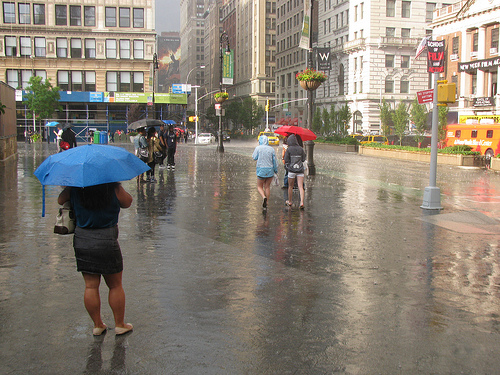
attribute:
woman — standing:
[57, 183, 133, 335]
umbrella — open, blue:
[36, 142, 151, 219]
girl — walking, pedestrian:
[280, 133, 307, 210]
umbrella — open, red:
[271, 123, 317, 143]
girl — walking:
[251, 130, 278, 211]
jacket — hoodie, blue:
[249, 134, 277, 178]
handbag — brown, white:
[52, 203, 73, 234]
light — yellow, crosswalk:
[187, 114, 194, 123]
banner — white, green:
[297, 0, 314, 52]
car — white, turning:
[194, 131, 216, 146]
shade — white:
[85, 72, 94, 85]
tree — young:
[379, 95, 391, 143]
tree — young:
[393, 97, 408, 143]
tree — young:
[409, 95, 426, 146]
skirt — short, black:
[71, 229, 125, 275]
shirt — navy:
[68, 182, 119, 229]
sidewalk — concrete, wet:
[3, 138, 499, 366]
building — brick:
[1, 1, 159, 132]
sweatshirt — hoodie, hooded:
[282, 132, 309, 174]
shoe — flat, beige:
[114, 321, 131, 336]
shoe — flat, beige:
[92, 325, 106, 337]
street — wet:
[222, 136, 499, 216]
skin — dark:
[79, 271, 132, 328]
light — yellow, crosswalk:
[435, 82, 458, 104]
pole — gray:
[420, 72, 442, 208]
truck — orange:
[438, 121, 498, 156]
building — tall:
[233, 2, 275, 135]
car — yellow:
[257, 128, 280, 148]